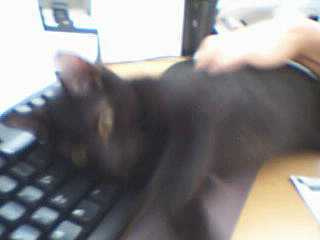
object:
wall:
[113, 8, 169, 53]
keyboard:
[0, 176, 16, 198]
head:
[1, 49, 151, 182]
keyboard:
[0, 199, 26, 226]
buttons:
[0, 202, 26, 227]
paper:
[287, 172, 320, 229]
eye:
[97, 109, 115, 140]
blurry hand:
[193, 12, 314, 76]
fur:
[189, 84, 252, 129]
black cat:
[2, 46, 318, 237]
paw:
[120, 209, 166, 240]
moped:
[111, 1, 170, 52]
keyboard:
[11, 159, 43, 184]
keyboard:
[17, 184, 45, 207]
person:
[195, 1, 320, 81]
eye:
[70, 143, 87, 170]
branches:
[0, 46, 140, 192]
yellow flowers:
[1, 48, 146, 193]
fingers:
[245, 26, 300, 70]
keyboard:
[50, 191, 71, 210]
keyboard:
[67, 170, 95, 198]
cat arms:
[110, 142, 241, 238]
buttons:
[6, 224, 35, 239]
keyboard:
[89, 187, 117, 203]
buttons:
[50, 217, 83, 240]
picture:
[0, 0, 315, 239]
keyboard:
[36, 174, 61, 190]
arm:
[125, 135, 212, 238]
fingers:
[207, 50, 246, 78]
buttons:
[29, 204, 62, 232]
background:
[1, 3, 182, 103]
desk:
[97, 52, 320, 240]